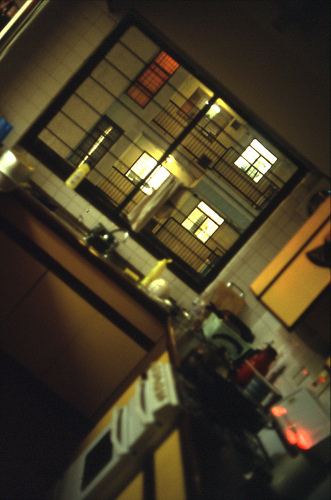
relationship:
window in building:
[29, 48, 313, 246] [0, 0, 330, 500]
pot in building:
[172, 308, 291, 411] [0, 0, 330, 500]